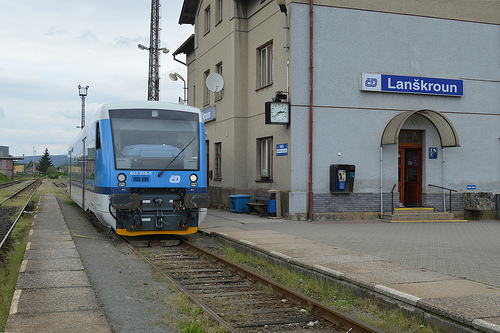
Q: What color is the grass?
A: Green.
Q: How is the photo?
A: Clear.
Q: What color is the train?
A: Blue.